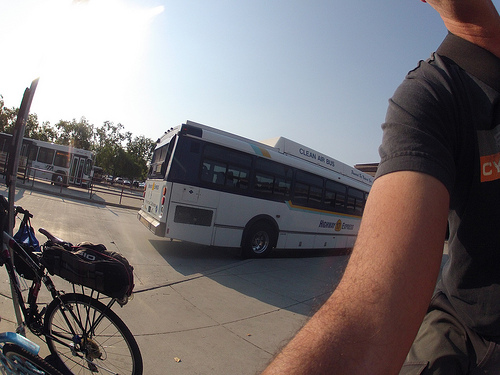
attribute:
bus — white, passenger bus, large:
[138, 121, 354, 258]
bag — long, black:
[42, 237, 136, 300]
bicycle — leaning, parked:
[1, 196, 143, 374]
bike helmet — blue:
[13, 209, 40, 280]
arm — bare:
[257, 140, 451, 375]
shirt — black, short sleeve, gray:
[375, 31, 499, 375]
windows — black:
[178, 156, 259, 194]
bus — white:
[0, 131, 96, 195]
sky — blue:
[1, 0, 384, 118]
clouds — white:
[4, 1, 175, 123]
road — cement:
[0, 200, 143, 238]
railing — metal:
[21, 161, 140, 206]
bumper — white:
[136, 207, 164, 238]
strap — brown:
[435, 28, 499, 90]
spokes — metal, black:
[47, 298, 144, 374]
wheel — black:
[242, 217, 273, 260]